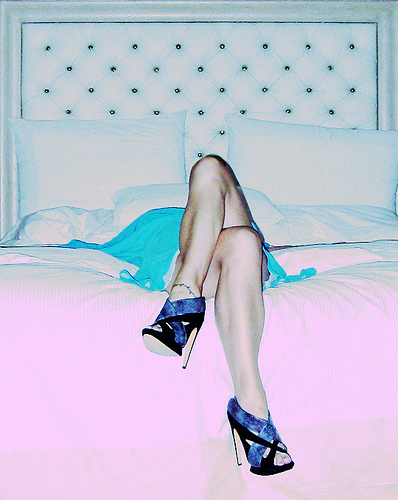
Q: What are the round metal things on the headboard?
A: Nail heads.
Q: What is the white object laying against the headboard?
A: Pillow.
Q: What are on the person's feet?
A: Shoes.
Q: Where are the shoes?
A: On the person's feet.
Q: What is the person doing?
A: Laying in a bed.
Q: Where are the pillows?
A: On the bed.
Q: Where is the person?
A: On the bed.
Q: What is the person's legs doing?
A: Crossing.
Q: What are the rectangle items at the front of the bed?
A: Pillows.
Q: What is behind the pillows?
A: A headboard.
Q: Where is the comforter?
A: On the bed.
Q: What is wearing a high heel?
A: Sexy leg.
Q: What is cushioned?
A: Head board.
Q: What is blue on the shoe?
A: Ribbon.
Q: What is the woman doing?
A: Laying on bed.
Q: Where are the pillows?
A: Top of bed.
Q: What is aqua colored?
A: Dress.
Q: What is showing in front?
A: Woman's legs.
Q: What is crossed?
A: Woman's leg.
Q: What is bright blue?
A: Dress.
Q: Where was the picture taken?
A: In a bedroom.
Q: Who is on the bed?
A: A woman.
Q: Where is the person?
A: On the bed.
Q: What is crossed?
A: Her legs.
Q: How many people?
A: 1.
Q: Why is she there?
A: Relaxing.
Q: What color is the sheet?
A: Pink.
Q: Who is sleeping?
A: The girl.